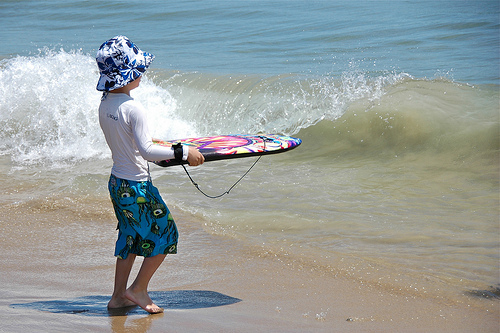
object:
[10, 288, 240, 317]
shadow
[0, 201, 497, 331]
sand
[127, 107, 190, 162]
sleeve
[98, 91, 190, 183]
shirt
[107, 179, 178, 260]
blue shorts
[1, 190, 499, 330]
beach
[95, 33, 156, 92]
hat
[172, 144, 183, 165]
strap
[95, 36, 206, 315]
boy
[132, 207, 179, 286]
leg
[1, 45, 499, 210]
waves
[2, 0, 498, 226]
ocean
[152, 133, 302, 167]
board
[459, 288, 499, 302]
shadow